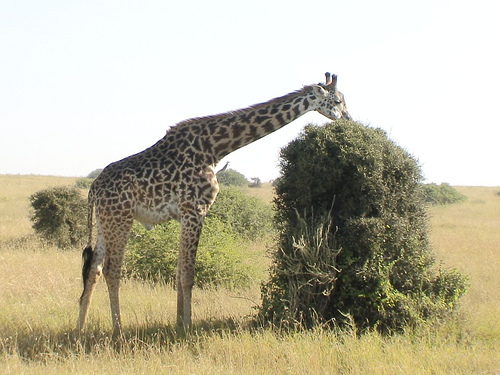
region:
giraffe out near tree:
[48, 48, 460, 353]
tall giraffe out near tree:
[69, 55, 386, 329]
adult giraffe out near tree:
[44, 51, 412, 339]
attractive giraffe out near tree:
[50, 41, 448, 336]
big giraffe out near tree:
[44, 47, 433, 344]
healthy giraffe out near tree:
[29, 45, 466, 335]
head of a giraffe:
[288, 61, 362, 136]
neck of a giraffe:
[180, 87, 315, 144]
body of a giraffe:
[87, 145, 218, 228]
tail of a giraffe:
[60, 184, 108, 297]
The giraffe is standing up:
[12, 20, 482, 358]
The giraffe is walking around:
[25, 51, 482, 351]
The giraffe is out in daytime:
[35, 37, 470, 367]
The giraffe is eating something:
[35, 50, 453, 365]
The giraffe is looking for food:
[33, 40, 466, 366]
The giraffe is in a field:
[15, 50, 476, 335]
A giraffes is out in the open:
[8, 35, 484, 351]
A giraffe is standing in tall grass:
[21, 62, 477, 362]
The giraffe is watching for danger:
[25, 41, 480, 342]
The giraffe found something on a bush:
[11, 34, 480, 348]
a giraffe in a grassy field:
[74, 73, 357, 360]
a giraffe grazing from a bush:
[74, 71, 427, 356]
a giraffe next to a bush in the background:
[212, 160, 248, 189]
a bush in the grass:
[26, 184, 92, 252]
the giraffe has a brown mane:
[167, 87, 316, 131]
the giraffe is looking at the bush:
[301, 72, 371, 169]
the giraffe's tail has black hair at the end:
[73, 183, 93, 300]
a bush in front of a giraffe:
[218, 159, 249, 190]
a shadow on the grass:
[8, 319, 283, 360]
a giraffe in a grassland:
[58, 69, 361, 345]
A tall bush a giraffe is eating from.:
[256, 117, 471, 330]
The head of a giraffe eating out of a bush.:
[308, 72, 352, 124]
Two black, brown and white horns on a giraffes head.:
[321, 72, 338, 91]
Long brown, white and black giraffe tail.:
[78, 201, 97, 304]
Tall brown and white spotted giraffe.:
[73, 70, 353, 343]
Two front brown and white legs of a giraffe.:
[171, 212, 202, 341]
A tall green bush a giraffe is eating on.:
[263, 119, 435, 330]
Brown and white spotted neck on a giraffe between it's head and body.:
[193, 88, 310, 164]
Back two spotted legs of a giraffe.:
[72, 218, 132, 342]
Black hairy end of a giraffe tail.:
[76, 246, 93, 303]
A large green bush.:
[244, 110, 471, 330]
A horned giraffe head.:
[301, 68, 363, 135]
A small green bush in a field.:
[21, 180, 103, 253]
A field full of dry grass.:
[1, 175, 498, 374]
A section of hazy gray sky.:
[0, 0, 499, 185]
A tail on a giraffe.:
[73, 179, 106, 303]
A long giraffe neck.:
[194, 83, 315, 169]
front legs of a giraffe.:
[156, 205, 214, 345]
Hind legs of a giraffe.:
[72, 209, 137, 342]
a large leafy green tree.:
[214, 163, 271, 196]